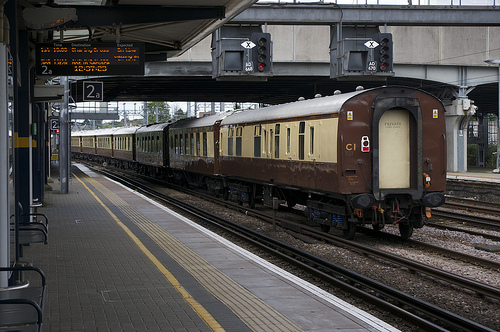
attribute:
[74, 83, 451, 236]
train — passenger, brown, yellow, last, white, tan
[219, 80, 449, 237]
car — last, brown, white, rear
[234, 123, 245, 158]
window — side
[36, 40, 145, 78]
sign — overhead, lighted, information, illuminated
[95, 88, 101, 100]
letter — white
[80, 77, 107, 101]
sign — black, white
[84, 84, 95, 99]
number — white, identification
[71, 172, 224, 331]
line — yellow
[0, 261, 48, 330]
bench — black, metal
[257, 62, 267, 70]
light — red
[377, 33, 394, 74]
light — signal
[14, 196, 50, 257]
bench — metal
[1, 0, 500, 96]
overpass — bridge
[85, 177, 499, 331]
tracks — rails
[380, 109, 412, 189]
door — rear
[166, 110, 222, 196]
car — brown, white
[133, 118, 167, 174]
car — brown, white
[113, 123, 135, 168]
car — brown, white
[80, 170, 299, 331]
lines — yellow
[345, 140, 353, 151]
letter — c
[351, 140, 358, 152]
letter — i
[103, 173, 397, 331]
line — white